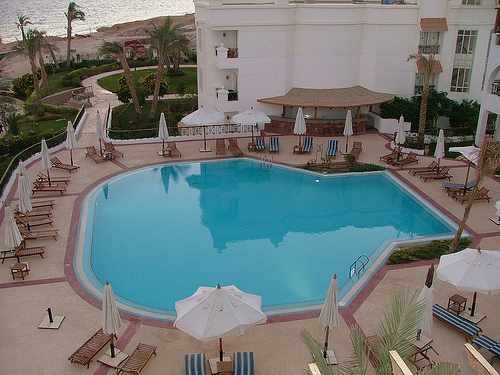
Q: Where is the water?
A: In background.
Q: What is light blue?
A: Pool water.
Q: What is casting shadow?
A: Building.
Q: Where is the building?
A: In background.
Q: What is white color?
A: Building.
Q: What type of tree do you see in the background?
A: Palm trees.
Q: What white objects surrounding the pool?
A: Beach umbrellas.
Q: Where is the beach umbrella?
A: Near the pool.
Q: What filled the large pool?
A: Water.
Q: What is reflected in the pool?
A: Building.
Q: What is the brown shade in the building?
A: Awnings.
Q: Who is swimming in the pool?
A: Not one.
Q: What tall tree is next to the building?
A: Palm trees.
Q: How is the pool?
A: Clear and blue.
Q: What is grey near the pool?
A: A walking path.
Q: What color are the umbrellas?
A: White.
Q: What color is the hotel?
A: White.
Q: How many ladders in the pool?
A: One.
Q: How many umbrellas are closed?
A: Thirteen.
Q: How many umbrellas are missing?
A: One.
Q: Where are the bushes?
A: By the pool.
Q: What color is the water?
A: Blue.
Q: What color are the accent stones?
A: Red.